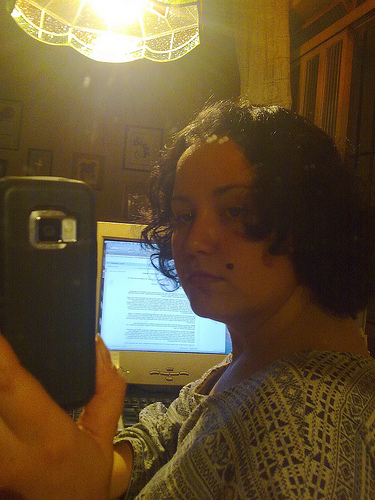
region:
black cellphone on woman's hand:
[0, 175, 94, 410]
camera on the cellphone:
[37, 219, 60, 240]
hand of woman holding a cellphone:
[0, 335, 127, 498]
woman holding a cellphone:
[0, 103, 374, 497]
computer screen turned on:
[96, 222, 233, 386]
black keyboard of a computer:
[66, 396, 174, 427]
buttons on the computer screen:
[148, 366, 187, 381]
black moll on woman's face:
[225, 261, 231, 267]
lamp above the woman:
[6, 0, 201, 62]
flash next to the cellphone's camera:
[62, 217, 75, 241]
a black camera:
[4, 175, 98, 409]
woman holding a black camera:
[2, 173, 128, 497]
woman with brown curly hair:
[140, 103, 370, 325]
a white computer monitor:
[95, 220, 234, 389]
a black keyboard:
[120, 391, 179, 438]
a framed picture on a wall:
[120, 121, 163, 176]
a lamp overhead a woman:
[10, 0, 201, 62]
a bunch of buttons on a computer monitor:
[148, 366, 189, 383]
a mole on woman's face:
[225, 262, 234, 272]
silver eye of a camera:
[27, 208, 69, 250]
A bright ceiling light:
[4, 0, 217, 63]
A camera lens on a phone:
[23, 202, 88, 260]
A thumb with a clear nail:
[93, 329, 126, 392]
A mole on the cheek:
[223, 255, 238, 277]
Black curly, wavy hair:
[145, 191, 173, 272]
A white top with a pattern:
[273, 395, 353, 475]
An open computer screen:
[106, 247, 149, 350]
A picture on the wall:
[66, 151, 113, 190]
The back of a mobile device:
[1, 165, 106, 411]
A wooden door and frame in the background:
[298, 4, 358, 119]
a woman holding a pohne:
[9, 131, 371, 406]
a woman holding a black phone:
[45, 113, 370, 420]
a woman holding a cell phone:
[14, 100, 350, 488]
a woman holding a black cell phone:
[3, 117, 370, 460]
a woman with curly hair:
[118, 73, 372, 300]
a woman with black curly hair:
[105, 93, 372, 342]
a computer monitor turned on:
[65, 192, 343, 443]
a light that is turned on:
[6, 1, 297, 104]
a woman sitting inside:
[76, 147, 329, 495]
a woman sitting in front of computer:
[31, 172, 369, 495]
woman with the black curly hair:
[8, 101, 371, 498]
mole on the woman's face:
[225, 263, 233, 269]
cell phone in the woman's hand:
[5, 178, 118, 491]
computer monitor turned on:
[97, 227, 226, 385]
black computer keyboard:
[80, 393, 177, 427]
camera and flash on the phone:
[29, 208, 72, 247]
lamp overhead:
[10, 1, 206, 63]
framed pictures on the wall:
[5, 100, 165, 188]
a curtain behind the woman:
[230, 5, 290, 108]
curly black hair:
[134, 102, 370, 317]